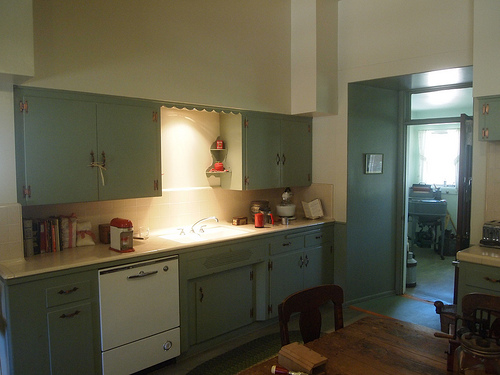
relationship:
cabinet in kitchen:
[12, 85, 163, 203] [2, 2, 497, 372]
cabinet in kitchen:
[219, 110, 313, 190] [2, 2, 497, 372]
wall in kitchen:
[1, 0, 497, 245] [2, 2, 497, 372]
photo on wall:
[361, 152, 385, 174] [345, 86, 396, 300]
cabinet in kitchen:
[13, 85, 163, 208] [2, 2, 497, 372]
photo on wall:
[364, 153, 385, 175] [322, 61, 456, 311]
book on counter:
[299, 196, 326, 224] [1, 203, 338, 282]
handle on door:
[89, 151, 97, 172] [97, 100, 160, 197]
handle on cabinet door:
[101, 150, 107, 169] [19, 95, 100, 206]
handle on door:
[275, 151, 280, 165] [246, 115, 282, 187]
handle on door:
[281, 152, 286, 165] [281, 117, 311, 187]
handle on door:
[200, 285, 206, 302] [193, 264, 255, 340]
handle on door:
[293, 250, 305, 270] [261, 243, 306, 321]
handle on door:
[302, 250, 311, 266] [300, 239, 338, 299]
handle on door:
[270, 151, 289, 168] [270, 149, 298, 171]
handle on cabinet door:
[199, 286, 205, 302] [191, 262, 263, 342]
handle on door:
[101, 150, 107, 169] [56, 100, 137, 170]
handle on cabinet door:
[86, 145, 111, 172] [27, 97, 107, 208]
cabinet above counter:
[219, 110, 313, 191] [10, 220, 328, 274]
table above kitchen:
[283, 300, 483, 371] [29, 48, 441, 347]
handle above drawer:
[53, 284, 84, 299] [24, 264, 127, 324]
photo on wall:
[364, 153, 385, 175] [352, 87, 395, 296]